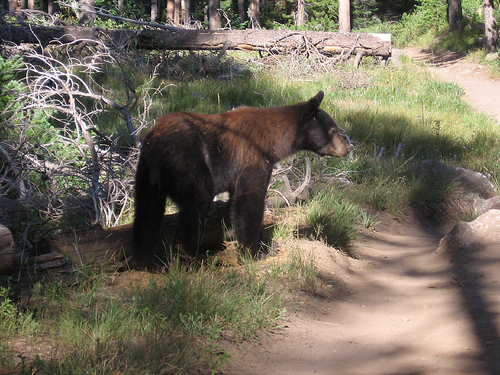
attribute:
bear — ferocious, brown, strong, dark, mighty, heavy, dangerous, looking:
[128, 87, 357, 261]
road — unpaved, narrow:
[424, 52, 500, 118]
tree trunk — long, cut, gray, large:
[141, 22, 393, 61]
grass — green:
[236, 62, 290, 87]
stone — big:
[434, 209, 499, 258]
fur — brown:
[235, 108, 282, 121]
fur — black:
[216, 174, 228, 190]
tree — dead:
[221, 29, 373, 59]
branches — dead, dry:
[51, 58, 142, 113]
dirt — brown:
[415, 223, 442, 238]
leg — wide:
[234, 164, 270, 246]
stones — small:
[326, 272, 347, 292]